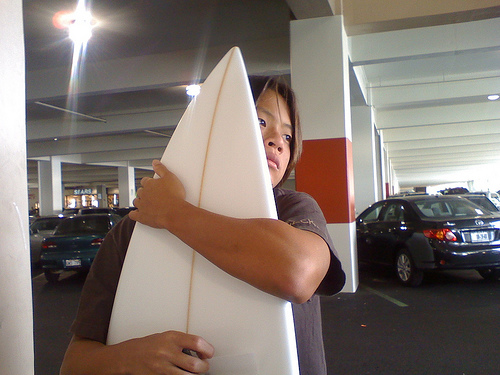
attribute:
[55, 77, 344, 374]
person — white, holding, asian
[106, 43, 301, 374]
surfboard — white, thin, white color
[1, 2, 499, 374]
building — paved, whie, lit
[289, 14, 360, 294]
pillar — red, brown, white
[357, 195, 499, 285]
car — parked, gray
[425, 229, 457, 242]
light — bright, glowing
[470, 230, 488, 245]
number plate — number plate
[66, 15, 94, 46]
light — bright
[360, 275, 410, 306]
line — white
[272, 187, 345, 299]
shirt — neutral